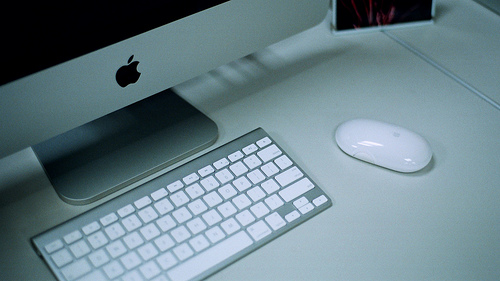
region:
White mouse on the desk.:
[333, 110, 435, 176]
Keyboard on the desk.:
[21, 124, 335, 279]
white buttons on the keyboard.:
[25, 131, 337, 279]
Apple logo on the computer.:
[111, 50, 146, 87]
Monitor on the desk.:
[2, 2, 330, 170]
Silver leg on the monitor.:
[36, 84, 222, 216]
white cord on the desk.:
[379, 21, 499, 113]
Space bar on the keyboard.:
[155, 228, 253, 280]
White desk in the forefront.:
[0, 3, 497, 277]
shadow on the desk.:
[200, 34, 357, 127]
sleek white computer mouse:
[331, 111, 436, 176]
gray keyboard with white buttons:
[26, 122, 336, 279]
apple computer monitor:
[2, 2, 342, 199]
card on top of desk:
[316, 0, 453, 34]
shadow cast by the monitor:
[2, 22, 376, 217]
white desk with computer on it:
[3, 0, 498, 273]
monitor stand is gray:
[23, 79, 221, 208]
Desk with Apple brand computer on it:
[0, 2, 499, 279]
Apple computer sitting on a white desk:
[0, 0, 498, 274]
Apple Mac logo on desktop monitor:
[110, 48, 144, 90]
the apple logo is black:
[95, 46, 217, 134]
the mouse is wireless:
[316, 119, 458, 205]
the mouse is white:
[335, 100, 492, 219]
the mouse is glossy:
[318, 96, 465, 194]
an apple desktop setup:
[55, 23, 435, 243]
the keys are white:
[123, 110, 355, 250]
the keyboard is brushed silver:
[55, 61, 305, 271]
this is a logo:
[100, 55, 152, 86]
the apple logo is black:
[86, 20, 183, 114]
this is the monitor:
[52, 14, 274, 180]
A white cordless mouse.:
[333, 115, 433, 175]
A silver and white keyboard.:
[30, 124, 335, 279]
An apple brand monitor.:
[0, 0, 331, 207]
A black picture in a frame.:
[329, 0, 437, 37]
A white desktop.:
[0, 0, 497, 279]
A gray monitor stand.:
[32, 85, 217, 209]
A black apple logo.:
[113, 50, 143, 93]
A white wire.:
[374, 28, 499, 111]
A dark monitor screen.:
[0, 0, 240, 87]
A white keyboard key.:
[277, 176, 316, 202]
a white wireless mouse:
[328, 113, 418, 170]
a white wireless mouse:
[295, 71, 471, 211]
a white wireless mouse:
[320, 99, 442, 196]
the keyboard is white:
[50, 149, 377, 274]